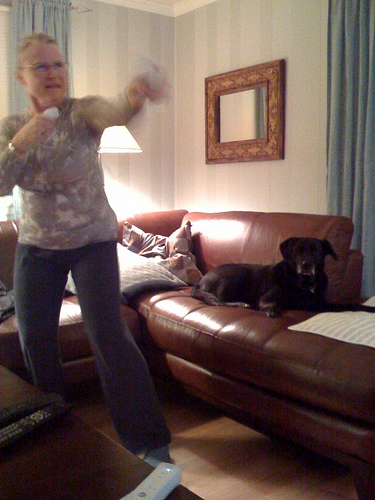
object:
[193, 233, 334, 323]
dog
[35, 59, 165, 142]
game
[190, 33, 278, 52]
wall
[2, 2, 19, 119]
curtains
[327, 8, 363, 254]
windows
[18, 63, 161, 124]
remotes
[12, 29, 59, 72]
hair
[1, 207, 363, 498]
couch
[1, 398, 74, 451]
remote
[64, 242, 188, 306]
throw pillow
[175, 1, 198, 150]
wall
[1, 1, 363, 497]
living room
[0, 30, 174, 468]
lady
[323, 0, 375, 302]
curtain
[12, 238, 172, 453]
pants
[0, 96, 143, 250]
shirt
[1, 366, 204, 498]
table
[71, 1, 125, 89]
wallpaper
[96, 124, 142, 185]
lamp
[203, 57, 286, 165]
frame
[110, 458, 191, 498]
controller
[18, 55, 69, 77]
glasses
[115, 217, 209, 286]
pillow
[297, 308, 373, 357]
towel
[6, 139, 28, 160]
watch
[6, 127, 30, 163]
wrist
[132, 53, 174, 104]
controller